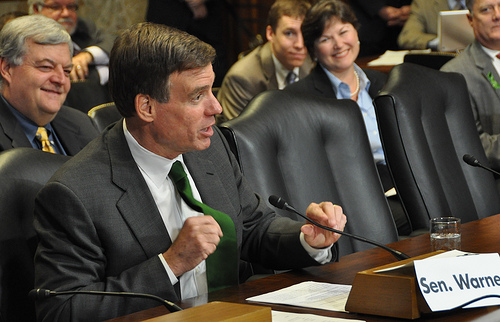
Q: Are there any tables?
A: Yes, there is a table.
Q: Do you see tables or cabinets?
A: Yes, there is a table.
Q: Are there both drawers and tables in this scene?
A: No, there is a table but no drawers.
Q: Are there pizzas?
A: No, there are no pizzas.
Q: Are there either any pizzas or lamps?
A: No, there are no pizzas or lamps.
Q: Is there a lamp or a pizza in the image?
A: No, there are no pizzas or lamps.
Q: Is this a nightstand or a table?
A: This is a table.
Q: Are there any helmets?
A: No, there are no helmets.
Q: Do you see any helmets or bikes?
A: No, there are no helmets or bikes.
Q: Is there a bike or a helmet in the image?
A: No, there are no helmets or bikes.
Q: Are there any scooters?
A: No, there are no scooters.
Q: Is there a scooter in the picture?
A: No, there are no scooters.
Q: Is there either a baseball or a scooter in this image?
A: No, there are no scooters or baseballs.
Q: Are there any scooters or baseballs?
A: No, there are no scooters or baseballs.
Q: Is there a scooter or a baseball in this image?
A: No, there are no scooters or baseballs.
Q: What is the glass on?
A: The glass is on the table.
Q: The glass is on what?
A: The glass is on the table.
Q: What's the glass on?
A: The glass is on the table.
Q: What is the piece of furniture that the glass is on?
A: The piece of furniture is a table.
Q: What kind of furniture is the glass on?
A: The glass is on the table.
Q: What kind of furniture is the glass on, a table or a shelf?
A: The glass is on a table.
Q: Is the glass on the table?
A: Yes, the glass is on the table.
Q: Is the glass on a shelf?
A: No, the glass is on the table.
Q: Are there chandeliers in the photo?
A: No, there are no chandeliers.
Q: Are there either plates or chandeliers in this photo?
A: No, there are no chandeliers or plates.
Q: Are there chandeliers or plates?
A: No, there are no chandeliers or plates.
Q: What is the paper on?
A: The paper is on the table.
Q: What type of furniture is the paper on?
A: The paper is on the table.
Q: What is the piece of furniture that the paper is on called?
A: The piece of furniture is a table.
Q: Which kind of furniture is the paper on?
A: The paper is on the table.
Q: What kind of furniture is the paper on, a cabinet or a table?
A: The paper is on a table.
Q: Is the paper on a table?
A: Yes, the paper is on a table.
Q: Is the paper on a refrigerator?
A: No, the paper is on a table.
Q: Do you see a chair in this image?
A: Yes, there is a chair.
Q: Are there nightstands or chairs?
A: Yes, there is a chair.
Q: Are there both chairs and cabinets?
A: No, there is a chair but no cabinets.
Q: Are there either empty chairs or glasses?
A: Yes, there is an empty chair.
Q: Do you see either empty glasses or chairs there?
A: Yes, there is an empty chair.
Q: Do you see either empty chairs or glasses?
A: Yes, there is an empty chair.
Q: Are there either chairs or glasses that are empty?
A: Yes, the chair is empty.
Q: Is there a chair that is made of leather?
A: Yes, there is a chair that is made of leather.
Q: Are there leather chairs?
A: Yes, there is a chair that is made of leather.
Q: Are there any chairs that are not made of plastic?
A: Yes, there is a chair that is made of leather.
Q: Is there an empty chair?
A: Yes, there is an empty chair.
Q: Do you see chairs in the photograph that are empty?
A: Yes, there is a chair that is empty.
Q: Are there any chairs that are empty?
A: Yes, there is a chair that is empty.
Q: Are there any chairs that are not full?
A: Yes, there is a empty chair.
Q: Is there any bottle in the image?
A: No, there are no bottles.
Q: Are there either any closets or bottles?
A: No, there are no bottles or closets.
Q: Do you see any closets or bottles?
A: No, there are no bottles or closets.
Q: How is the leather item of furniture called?
A: The piece of furniture is a chair.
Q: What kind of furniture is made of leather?
A: The furniture is a chair.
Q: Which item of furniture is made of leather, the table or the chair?
A: The chair is made of leather.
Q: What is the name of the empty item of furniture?
A: The piece of furniture is a chair.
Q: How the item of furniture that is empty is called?
A: The piece of furniture is a chair.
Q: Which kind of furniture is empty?
A: The furniture is a chair.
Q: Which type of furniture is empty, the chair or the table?
A: The chair is empty.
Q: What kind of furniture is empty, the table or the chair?
A: The chair is empty.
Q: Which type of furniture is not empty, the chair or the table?
A: The table is not empty.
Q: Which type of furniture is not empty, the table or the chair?
A: The table is not empty.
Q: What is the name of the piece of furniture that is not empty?
A: The piece of furniture is a table.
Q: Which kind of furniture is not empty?
A: The furniture is a table.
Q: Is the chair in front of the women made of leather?
A: Yes, the chair is made of leather.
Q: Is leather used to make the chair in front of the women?
A: Yes, the chair is made of leather.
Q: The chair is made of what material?
A: The chair is made of leather.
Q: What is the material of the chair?
A: The chair is made of leather.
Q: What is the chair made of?
A: The chair is made of leather.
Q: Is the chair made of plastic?
A: No, the chair is made of leather.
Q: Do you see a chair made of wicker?
A: No, there is a chair but it is made of leather.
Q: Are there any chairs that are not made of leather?
A: No, there is a chair but it is made of leather.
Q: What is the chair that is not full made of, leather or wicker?
A: The chair is made of leather.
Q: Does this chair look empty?
A: Yes, the chair is empty.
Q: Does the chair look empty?
A: Yes, the chair is empty.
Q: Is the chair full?
A: No, the chair is empty.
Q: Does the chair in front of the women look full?
A: No, the chair is empty.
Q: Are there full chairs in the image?
A: No, there is a chair but it is empty.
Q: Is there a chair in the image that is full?
A: No, there is a chair but it is empty.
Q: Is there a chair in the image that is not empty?
A: No, there is a chair but it is empty.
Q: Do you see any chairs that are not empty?
A: No, there is a chair but it is empty.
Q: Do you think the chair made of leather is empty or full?
A: The chair is empty.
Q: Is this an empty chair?
A: Yes, this is an empty chair.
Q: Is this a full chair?
A: No, this is an empty chair.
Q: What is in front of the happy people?
A: The chair is in front of the women.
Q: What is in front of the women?
A: The chair is in front of the women.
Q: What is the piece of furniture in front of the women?
A: The piece of furniture is a chair.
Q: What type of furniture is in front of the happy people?
A: The piece of furniture is a chair.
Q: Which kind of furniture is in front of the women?
A: The piece of furniture is a chair.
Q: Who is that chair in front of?
A: The chair is in front of the women.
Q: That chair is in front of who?
A: The chair is in front of the women.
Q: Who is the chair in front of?
A: The chair is in front of the women.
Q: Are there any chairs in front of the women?
A: Yes, there is a chair in front of the women.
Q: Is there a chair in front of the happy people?
A: Yes, there is a chair in front of the women.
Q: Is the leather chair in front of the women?
A: Yes, the chair is in front of the women.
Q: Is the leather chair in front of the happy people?
A: Yes, the chair is in front of the women.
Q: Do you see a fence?
A: No, there are no fences.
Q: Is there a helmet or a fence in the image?
A: No, there are no fences or helmets.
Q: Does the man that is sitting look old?
A: Yes, the man is old.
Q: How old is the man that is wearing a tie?
A: The man is old.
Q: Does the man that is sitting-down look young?
A: No, the man is old.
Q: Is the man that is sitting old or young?
A: The man is old.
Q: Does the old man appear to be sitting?
A: Yes, the man is sitting.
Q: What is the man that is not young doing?
A: The man is sitting.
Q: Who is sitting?
A: The man is sitting.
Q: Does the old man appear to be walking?
A: No, the man is sitting.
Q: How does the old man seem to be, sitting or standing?
A: The man is sitting.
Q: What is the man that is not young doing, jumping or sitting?
A: The man is sitting.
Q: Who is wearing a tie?
A: The man is wearing a tie.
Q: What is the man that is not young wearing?
A: The man is wearing a tie.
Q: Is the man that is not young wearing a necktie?
A: Yes, the man is wearing a necktie.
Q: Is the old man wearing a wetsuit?
A: No, the man is wearing a necktie.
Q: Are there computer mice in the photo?
A: No, there are no computer mice.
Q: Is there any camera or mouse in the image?
A: No, there are no computer mice or cameras.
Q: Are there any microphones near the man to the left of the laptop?
A: Yes, there is a microphone near the man.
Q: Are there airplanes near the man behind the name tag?
A: No, there is a microphone near the man.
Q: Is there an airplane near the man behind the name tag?
A: No, there is a microphone near the man.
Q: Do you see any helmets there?
A: No, there are no helmets.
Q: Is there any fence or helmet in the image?
A: No, there are no helmets or fences.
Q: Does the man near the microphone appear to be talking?
A: Yes, the man is talking.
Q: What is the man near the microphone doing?
A: The man is talking.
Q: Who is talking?
A: The man is talking.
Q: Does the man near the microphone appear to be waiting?
A: No, the man is talking.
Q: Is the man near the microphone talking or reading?
A: The man is talking.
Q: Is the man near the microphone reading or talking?
A: The man is talking.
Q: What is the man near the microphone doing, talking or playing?
A: The man is talking.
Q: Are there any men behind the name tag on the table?
A: Yes, there is a man behind the name tag.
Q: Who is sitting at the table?
A: The man is sitting at the table.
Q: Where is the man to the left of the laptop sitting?
A: The man is sitting at the table.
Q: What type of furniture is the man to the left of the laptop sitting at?
A: The man is sitting at the table.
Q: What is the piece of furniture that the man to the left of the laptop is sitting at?
A: The piece of furniture is a table.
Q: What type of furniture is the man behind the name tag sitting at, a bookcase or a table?
A: The man is sitting at a table.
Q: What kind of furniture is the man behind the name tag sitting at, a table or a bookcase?
A: The man is sitting at a table.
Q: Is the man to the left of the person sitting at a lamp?
A: No, the man is sitting at the table.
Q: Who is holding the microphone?
A: The man is holding the microphone.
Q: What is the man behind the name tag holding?
A: The man is holding the microphone.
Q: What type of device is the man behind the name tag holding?
A: The man is holding the microphone.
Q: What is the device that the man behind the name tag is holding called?
A: The device is a microphone.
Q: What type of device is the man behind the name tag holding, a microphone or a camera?
A: The man is holding a microphone.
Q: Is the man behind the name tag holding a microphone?
A: Yes, the man is holding a microphone.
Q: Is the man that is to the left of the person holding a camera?
A: No, the man is holding a microphone.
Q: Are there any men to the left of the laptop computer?
A: Yes, there is a man to the left of the laptop computer.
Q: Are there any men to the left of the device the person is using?
A: Yes, there is a man to the left of the laptop computer.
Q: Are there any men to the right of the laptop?
A: No, the man is to the left of the laptop.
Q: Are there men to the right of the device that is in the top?
A: No, the man is to the left of the laptop.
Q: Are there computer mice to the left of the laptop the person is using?
A: No, there is a man to the left of the laptop computer.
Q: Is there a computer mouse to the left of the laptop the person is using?
A: No, there is a man to the left of the laptop computer.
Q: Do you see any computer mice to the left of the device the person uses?
A: No, there is a man to the left of the laptop computer.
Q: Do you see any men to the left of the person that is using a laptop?
A: Yes, there is a man to the left of the person.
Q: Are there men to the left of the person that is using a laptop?
A: Yes, there is a man to the left of the person.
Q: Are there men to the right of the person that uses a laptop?
A: No, the man is to the left of the person.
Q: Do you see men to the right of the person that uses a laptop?
A: No, the man is to the left of the person.